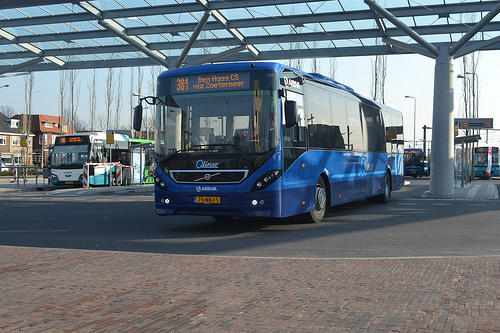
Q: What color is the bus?
A: Blue.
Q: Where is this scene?
A: Parking lot.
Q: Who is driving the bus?
A: Bus driver.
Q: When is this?
A: Daytime.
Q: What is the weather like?
A: Fair.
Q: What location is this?
A: Bus station.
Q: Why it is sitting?
A: Parked.